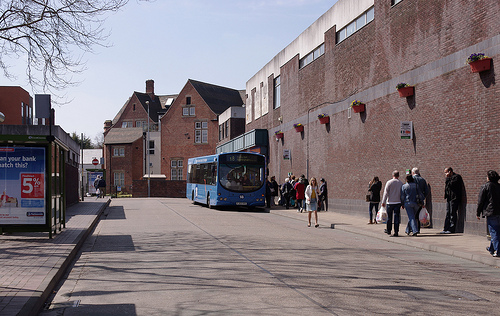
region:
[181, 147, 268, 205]
A blue bus.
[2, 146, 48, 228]
A sign on a sidewalk.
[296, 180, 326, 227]
A woman walking on street.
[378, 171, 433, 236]
A couple carrying plastic bags.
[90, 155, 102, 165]
A Red and white street sign.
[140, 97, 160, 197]
A gray light pole.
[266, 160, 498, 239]
People walking on sidewalk.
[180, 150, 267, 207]
A bus stopped on street.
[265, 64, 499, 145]
A row of plants on building.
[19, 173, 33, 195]
The number 5 on a sign.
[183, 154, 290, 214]
A blue town bus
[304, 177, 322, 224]
A blond woman in white top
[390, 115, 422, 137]
A bus sign mounted on the wall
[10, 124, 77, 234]
A bus booth on the sidewalk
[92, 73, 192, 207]
A brick 2-3 story building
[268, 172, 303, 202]
A group of people waiting for the bus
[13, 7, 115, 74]
A tree with dry branches with no leaves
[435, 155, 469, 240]
A bald and tall mam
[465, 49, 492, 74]
A flower pot decorated on the wall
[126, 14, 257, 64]
A clear and sunny day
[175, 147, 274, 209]
blue bus on the street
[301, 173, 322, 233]
person on the street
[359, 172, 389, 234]
person on the street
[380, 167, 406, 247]
person on the street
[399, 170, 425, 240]
person on the street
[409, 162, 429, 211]
person on the street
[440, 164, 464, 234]
person on the street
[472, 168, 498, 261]
person on the street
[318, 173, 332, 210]
person on the street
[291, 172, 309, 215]
person on the street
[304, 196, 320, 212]
A blue skirt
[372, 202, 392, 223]
A plastic bag in the mans hand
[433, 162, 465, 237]
A man leaning agianst the wall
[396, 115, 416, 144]
Sign on the wall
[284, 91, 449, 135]
a row of flower planters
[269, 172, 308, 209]
A group by the bus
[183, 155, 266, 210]
A blue bus parked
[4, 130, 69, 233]
A green bus stop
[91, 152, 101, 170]
A street sign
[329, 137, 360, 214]
A brick wall for the building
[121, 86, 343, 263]
the bus is blue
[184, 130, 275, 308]
the bus is blue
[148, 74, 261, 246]
the bus is blue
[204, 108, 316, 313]
the bus is blue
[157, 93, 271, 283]
the bus is blue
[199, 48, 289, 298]
the bus is blue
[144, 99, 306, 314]
the bus is blue